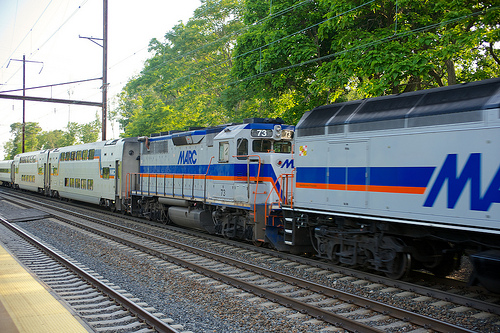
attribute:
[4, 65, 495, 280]
train — long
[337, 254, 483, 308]
track — brown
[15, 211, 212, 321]
track — empty, brown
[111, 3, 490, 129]
trees — green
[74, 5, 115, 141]
pole — tall, wooden, long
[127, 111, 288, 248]
engine — colorful, gray, blue, orange, present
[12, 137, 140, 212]
cars — white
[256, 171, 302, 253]
steps — orange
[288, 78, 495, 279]
train car — gray, orange, blue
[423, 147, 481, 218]
letter — large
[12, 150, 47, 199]
car — white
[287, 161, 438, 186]
line — blue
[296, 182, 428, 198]
line — orange